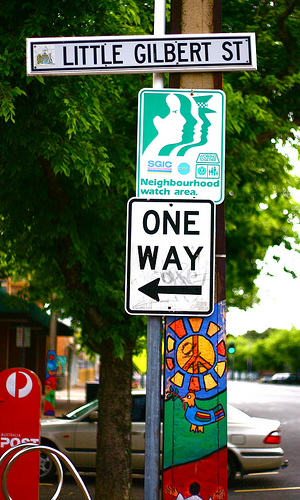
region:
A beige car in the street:
[24, 377, 294, 499]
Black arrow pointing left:
[135, 274, 208, 304]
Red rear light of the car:
[261, 426, 285, 447]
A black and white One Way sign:
[120, 194, 220, 322]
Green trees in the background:
[236, 332, 298, 369]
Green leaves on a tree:
[46, 93, 114, 167]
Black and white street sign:
[22, 34, 261, 76]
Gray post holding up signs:
[140, 316, 166, 489]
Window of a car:
[127, 390, 150, 427]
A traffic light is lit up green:
[223, 338, 239, 359]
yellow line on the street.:
[252, 483, 288, 493]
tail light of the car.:
[266, 430, 278, 443]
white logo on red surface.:
[6, 374, 31, 401]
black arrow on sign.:
[136, 276, 204, 299]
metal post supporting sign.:
[147, 368, 159, 464]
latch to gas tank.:
[230, 433, 245, 444]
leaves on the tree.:
[69, 153, 95, 168]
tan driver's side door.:
[79, 430, 93, 441]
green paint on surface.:
[180, 436, 198, 453]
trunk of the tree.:
[97, 398, 129, 459]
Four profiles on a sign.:
[129, 82, 243, 198]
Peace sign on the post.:
[171, 327, 223, 384]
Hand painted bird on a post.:
[173, 377, 228, 446]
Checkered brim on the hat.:
[187, 82, 220, 155]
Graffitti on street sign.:
[132, 225, 219, 314]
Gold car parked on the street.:
[49, 390, 134, 483]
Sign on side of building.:
[12, 312, 31, 353]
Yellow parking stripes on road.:
[241, 462, 272, 498]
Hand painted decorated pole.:
[41, 338, 63, 417]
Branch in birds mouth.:
[163, 378, 196, 429]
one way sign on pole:
[121, 194, 218, 498]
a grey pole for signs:
[142, 316, 162, 498]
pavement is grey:
[37, 378, 298, 498]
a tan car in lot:
[41, 387, 293, 489]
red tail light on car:
[259, 427, 283, 446]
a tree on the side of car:
[1, 0, 298, 498]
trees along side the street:
[225, 324, 297, 380]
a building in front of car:
[2, 289, 77, 411]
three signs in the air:
[23, 28, 262, 319]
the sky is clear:
[43, 0, 298, 336]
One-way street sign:
[126, 196, 215, 315]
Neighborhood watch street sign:
[134, 85, 226, 209]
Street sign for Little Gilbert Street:
[24, 34, 255, 70]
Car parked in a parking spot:
[45, 381, 292, 485]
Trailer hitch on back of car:
[279, 455, 294, 467]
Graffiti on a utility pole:
[165, 316, 227, 499]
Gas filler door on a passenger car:
[228, 432, 249, 446]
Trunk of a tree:
[97, 348, 133, 498]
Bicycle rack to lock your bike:
[0, 441, 95, 498]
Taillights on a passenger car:
[262, 427, 282, 446]